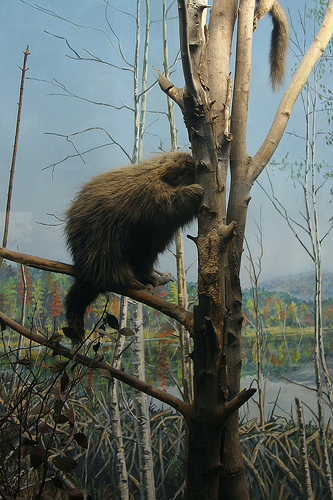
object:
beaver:
[57, 149, 210, 342]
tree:
[18, 262, 33, 329]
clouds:
[10, 207, 35, 247]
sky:
[64, 0, 104, 31]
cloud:
[5, 15, 41, 46]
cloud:
[28, 103, 81, 127]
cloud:
[86, 66, 128, 100]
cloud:
[268, 227, 294, 262]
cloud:
[27, 179, 65, 214]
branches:
[256, 1, 333, 170]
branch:
[1, 40, 43, 243]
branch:
[40, 121, 130, 182]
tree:
[245, 290, 262, 333]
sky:
[294, 1, 331, 33]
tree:
[284, 299, 298, 329]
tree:
[47, 282, 64, 327]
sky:
[287, 138, 304, 160]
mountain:
[256, 270, 331, 346]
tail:
[61, 280, 95, 349]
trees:
[93, 293, 110, 333]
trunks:
[173, 0, 255, 500]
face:
[172, 150, 195, 185]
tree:
[262, 296, 281, 328]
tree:
[153, 281, 177, 338]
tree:
[0, 274, 18, 319]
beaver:
[252, 0, 291, 90]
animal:
[252, 0, 288, 92]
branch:
[15, 324, 188, 415]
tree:
[300, 299, 311, 327]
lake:
[298, 384, 329, 426]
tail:
[267, 1, 290, 94]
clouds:
[0, 57, 18, 108]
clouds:
[264, 264, 295, 282]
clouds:
[250, 195, 263, 220]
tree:
[29, 269, 47, 333]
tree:
[0, 1, 329, 497]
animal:
[59, 148, 208, 342]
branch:
[28, 254, 190, 328]